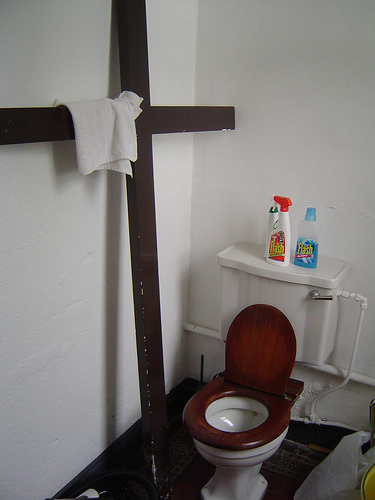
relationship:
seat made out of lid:
[181, 298, 296, 451] [223, 303, 299, 399]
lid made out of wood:
[223, 303, 299, 399] [227, 304, 295, 396]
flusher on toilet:
[308, 288, 334, 303] [183, 239, 352, 498]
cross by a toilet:
[18, 17, 244, 492] [183, 239, 352, 498]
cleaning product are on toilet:
[293, 207, 321, 269] [207, 327, 305, 450]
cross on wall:
[0, 0, 240, 500] [4, 4, 184, 389]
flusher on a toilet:
[308, 288, 334, 303] [203, 335, 292, 474]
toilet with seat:
[216, 241, 348, 369] [182, 302, 306, 452]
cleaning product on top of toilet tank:
[262, 200, 275, 252] [215, 241, 352, 366]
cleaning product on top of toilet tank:
[261, 186, 287, 269] [215, 241, 352, 366]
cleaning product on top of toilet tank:
[296, 201, 321, 266] [215, 241, 352, 366]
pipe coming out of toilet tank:
[295, 268, 366, 419] [218, 238, 356, 367]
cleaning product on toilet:
[263, 205, 279, 259] [183, 239, 352, 498]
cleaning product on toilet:
[265, 193, 292, 268] [183, 239, 352, 498]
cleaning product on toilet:
[293, 207, 321, 269] [183, 239, 352, 498]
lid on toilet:
[216, 303, 296, 397] [183, 239, 352, 498]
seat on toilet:
[182, 302, 306, 452] [183, 239, 352, 498]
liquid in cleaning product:
[295, 241, 316, 267] [293, 207, 321, 269]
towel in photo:
[50, 89, 146, 175] [4, 2, 373, 495]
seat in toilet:
[182, 302, 306, 452] [183, 239, 352, 498]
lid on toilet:
[223, 303, 299, 399] [168, 306, 337, 497]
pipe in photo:
[310, 309, 369, 417] [4, 2, 373, 495]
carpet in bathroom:
[269, 445, 302, 498] [1, 0, 374, 498]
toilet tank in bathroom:
[219, 242, 350, 364] [1, 0, 374, 498]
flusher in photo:
[308, 288, 334, 303] [4, 2, 373, 495]